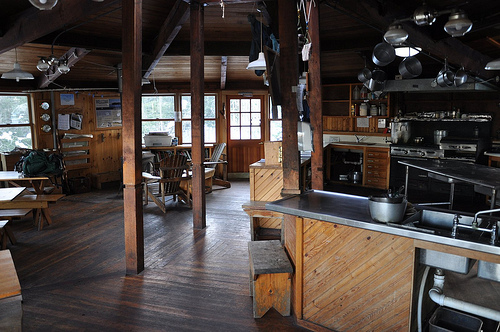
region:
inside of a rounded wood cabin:
[4, 4, 499, 329]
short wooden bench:
[248, 239, 294, 317]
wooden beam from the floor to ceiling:
[118, 2, 148, 276]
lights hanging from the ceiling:
[8, 19, 277, 84]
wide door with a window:
[226, 89, 263, 176]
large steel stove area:
[396, 109, 491, 212]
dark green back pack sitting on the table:
[12, 149, 63, 176]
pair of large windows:
[127, 94, 217, 147]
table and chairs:
[129, 130, 224, 210]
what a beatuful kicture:
[2, 0, 496, 326]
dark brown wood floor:
[0, 174, 325, 329]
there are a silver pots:
[365, 188, 433, 223]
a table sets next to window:
[135, 134, 234, 220]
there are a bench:
[244, 231, 295, 317]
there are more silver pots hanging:
[362, 17, 487, 95]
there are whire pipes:
[406, 267, 498, 330]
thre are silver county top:
[264, 180, 499, 257]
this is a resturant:
[4, 1, 497, 331]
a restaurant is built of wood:
[18, 3, 499, 323]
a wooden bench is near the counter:
[243, 232, 295, 324]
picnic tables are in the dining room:
[2, 165, 64, 240]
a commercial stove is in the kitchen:
[385, 76, 497, 205]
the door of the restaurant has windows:
[223, 89, 266, 180]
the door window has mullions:
[227, 93, 266, 143]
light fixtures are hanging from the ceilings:
[6, 19, 493, 88]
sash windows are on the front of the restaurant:
[1, 90, 219, 167]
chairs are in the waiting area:
[120, 125, 234, 217]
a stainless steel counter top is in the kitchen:
[263, 181, 498, 268]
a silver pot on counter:
[353, 167, 453, 232]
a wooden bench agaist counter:
[228, 222, 311, 325]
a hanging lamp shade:
[4, 46, 38, 87]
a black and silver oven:
[376, 137, 453, 208]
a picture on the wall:
[107, 97, 127, 114]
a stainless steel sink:
[397, 199, 494, 247]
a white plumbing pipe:
[426, 274, 497, 323]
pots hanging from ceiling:
[364, 42, 475, 101]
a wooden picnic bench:
[3, 186, 60, 238]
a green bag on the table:
[16, 129, 66, 198]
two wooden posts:
[90, 20, 210, 269]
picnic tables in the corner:
[0, 175, 65, 230]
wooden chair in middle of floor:
[136, 150, 183, 212]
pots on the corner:
[361, 190, 406, 238]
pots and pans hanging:
[368, 7, 484, 68]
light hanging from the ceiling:
[245, 52, 272, 87]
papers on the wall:
[60, 95, 81, 137]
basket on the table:
[146, 112, 179, 153]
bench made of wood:
[238, 237, 295, 330]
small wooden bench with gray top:
[245, 235, 292, 320]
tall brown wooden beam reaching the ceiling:
[115, 4, 149, 278]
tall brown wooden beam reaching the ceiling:
[187, 4, 207, 231]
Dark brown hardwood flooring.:
[3, 168, 336, 328]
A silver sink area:
[392, 194, 499, 257]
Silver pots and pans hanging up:
[344, 32, 494, 128]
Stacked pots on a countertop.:
[348, 181, 418, 233]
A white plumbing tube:
[425, 270, 499, 321]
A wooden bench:
[244, 235, 292, 319]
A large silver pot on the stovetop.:
[392, 118, 409, 142]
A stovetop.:
[387, 123, 448, 153]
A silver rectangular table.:
[397, 151, 499, 197]